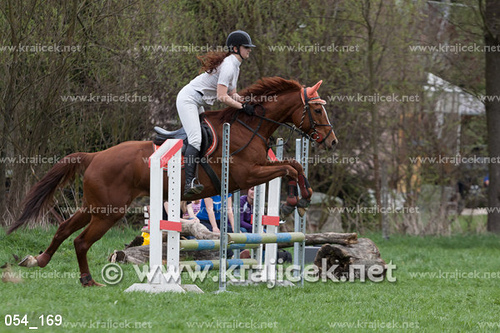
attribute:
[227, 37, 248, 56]
helmet — black, grey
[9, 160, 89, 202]
horse tail — brown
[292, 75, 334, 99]
cover — orange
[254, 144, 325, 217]
legs — brown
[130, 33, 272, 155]
girl — brown haired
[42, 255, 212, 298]
area — green, grassy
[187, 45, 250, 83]
hair — brown, curly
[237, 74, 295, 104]
mane — brown, horse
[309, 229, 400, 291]
log — large